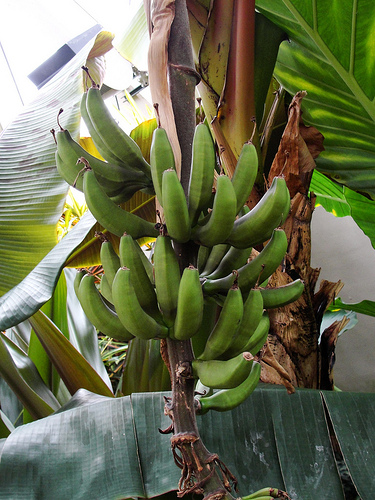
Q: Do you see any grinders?
A: No, there are no grinders.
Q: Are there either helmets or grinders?
A: No, there are no grinders or helmets.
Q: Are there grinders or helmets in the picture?
A: No, there are no grinders or helmets.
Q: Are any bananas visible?
A: Yes, there is a banana.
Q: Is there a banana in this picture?
A: Yes, there is a banana.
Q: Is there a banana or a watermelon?
A: Yes, there is a banana.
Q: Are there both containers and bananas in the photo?
A: No, there is a banana but no containers.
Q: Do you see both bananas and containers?
A: No, there is a banana but no containers.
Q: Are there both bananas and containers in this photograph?
A: No, there is a banana but no containers.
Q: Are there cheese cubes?
A: No, there are no cheese cubes.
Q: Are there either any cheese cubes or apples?
A: No, there are no cheese cubes or apples.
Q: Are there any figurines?
A: No, there are no figurines.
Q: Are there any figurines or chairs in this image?
A: No, there are no figurines or chairs.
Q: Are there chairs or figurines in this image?
A: No, there are no figurines or chairs.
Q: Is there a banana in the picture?
A: Yes, there is a banana.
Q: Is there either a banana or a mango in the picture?
A: Yes, there is a banana.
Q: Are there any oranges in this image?
A: No, there are no oranges.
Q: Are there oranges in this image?
A: No, there are no oranges.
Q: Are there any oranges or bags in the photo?
A: No, there are no oranges or bags.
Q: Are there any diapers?
A: No, there are no diapers.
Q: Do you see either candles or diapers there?
A: No, there are no diapers or candles.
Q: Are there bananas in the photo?
A: Yes, there is a banana.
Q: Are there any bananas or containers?
A: Yes, there is a banana.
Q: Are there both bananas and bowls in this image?
A: No, there is a banana but no bowls.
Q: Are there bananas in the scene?
A: Yes, there is a banana.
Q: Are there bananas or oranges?
A: Yes, there is a banana.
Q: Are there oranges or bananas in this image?
A: Yes, there is a banana.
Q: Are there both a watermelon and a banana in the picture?
A: No, there is a banana but no watermelons.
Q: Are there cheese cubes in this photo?
A: No, there are no cheese cubes.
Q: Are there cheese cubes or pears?
A: No, there are no cheese cubes or pears.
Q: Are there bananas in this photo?
A: Yes, there is a banana.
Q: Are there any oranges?
A: No, there are no oranges.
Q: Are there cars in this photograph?
A: No, there are no cars.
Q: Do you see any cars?
A: No, there are no cars.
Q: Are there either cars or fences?
A: No, there are no cars or fences.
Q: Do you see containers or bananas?
A: Yes, there is a banana.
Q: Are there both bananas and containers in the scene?
A: No, there is a banana but no containers.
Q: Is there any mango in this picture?
A: No, there are no mangoes.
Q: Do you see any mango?
A: No, there are no mangoes.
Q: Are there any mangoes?
A: No, there are no mangoes.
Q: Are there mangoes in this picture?
A: No, there are no mangoes.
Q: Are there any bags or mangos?
A: No, there are no mangos or bags.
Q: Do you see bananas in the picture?
A: Yes, there is a banana.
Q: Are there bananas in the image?
A: Yes, there is a banana.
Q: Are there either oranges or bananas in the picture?
A: Yes, there is a banana.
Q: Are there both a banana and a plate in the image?
A: No, there is a banana but no plates.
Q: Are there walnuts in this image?
A: No, there are no walnuts.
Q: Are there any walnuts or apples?
A: No, there are no walnuts or apples.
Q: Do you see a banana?
A: Yes, there is a banana.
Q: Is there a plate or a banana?
A: Yes, there is a banana.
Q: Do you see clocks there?
A: No, there are no clocks.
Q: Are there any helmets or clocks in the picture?
A: No, there are no clocks or helmets.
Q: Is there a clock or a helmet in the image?
A: No, there are no clocks or helmets.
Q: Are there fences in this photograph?
A: No, there are no fences.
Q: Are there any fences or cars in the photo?
A: No, there are no fences or cars.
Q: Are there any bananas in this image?
A: Yes, there is a banana.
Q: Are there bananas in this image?
A: Yes, there is a banana.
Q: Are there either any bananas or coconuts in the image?
A: Yes, there is a banana.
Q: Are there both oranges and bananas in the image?
A: No, there is a banana but no oranges.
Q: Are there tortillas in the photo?
A: No, there are no tortillas.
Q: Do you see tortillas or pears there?
A: No, there are no tortillas or pears.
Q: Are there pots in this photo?
A: No, there are no pots.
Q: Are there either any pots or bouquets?
A: No, there are no pots or bouquets.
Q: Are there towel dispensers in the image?
A: No, there are no towel dispensers.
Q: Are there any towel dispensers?
A: No, there are no towel dispensers.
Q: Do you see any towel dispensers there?
A: No, there are no towel dispensers.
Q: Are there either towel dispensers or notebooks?
A: No, there are no towel dispensers or notebooks.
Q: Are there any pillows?
A: No, there are no pillows.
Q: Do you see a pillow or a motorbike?
A: No, there are no pillows or motorcycles.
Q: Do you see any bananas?
A: Yes, there is a banana.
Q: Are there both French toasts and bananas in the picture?
A: No, there is a banana but no French toasts.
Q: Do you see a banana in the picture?
A: Yes, there is a banana.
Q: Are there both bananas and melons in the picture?
A: No, there is a banana but no melons.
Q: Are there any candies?
A: No, there are no candies.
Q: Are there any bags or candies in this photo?
A: No, there are no candies or bags.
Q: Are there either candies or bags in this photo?
A: No, there are no candies or bags.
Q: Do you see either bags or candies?
A: No, there are no candies or bags.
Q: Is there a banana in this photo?
A: Yes, there is a banana.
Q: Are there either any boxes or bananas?
A: Yes, there is a banana.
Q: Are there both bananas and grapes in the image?
A: No, there is a banana but no grapes.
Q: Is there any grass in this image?
A: Yes, there is grass.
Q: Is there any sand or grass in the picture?
A: Yes, there is grass.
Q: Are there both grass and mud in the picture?
A: No, there is grass but no mud.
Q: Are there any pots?
A: No, there are no pots.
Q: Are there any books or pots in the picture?
A: No, there are no pots or books.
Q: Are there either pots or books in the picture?
A: No, there are no pots or books.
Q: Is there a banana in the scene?
A: Yes, there are bananas.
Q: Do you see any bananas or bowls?
A: Yes, there are bananas.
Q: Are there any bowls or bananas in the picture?
A: Yes, there are bananas.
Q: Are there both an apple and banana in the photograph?
A: No, there are bananas but no apples.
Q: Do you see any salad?
A: No, there is no salad.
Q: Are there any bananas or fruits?
A: Yes, there is a banana.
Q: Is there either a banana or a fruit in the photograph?
A: Yes, there is a banana.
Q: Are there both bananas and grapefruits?
A: No, there is a banana but no grapefruits.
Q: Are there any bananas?
A: Yes, there is a banana.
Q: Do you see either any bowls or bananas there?
A: Yes, there is a banana.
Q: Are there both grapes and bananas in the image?
A: No, there is a banana but no grapes.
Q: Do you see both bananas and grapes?
A: No, there is a banana but no grapes.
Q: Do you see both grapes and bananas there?
A: No, there is a banana but no grapes.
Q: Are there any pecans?
A: No, there are no pecans.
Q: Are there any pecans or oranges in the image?
A: No, there are no pecans or oranges.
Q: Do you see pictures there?
A: No, there are no pictures.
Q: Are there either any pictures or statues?
A: No, there are no pictures or statues.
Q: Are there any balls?
A: No, there are no balls.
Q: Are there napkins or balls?
A: No, there are no balls or napkins.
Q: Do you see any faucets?
A: No, there are no faucets.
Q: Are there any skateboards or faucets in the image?
A: No, there are no faucets or skateboards.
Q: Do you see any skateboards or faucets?
A: No, there are no faucets or skateboards.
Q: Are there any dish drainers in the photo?
A: No, there are no dish drainers.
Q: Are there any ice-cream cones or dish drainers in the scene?
A: No, there are no dish drainers or ice-cream cones.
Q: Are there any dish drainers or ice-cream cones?
A: No, there are no dish drainers or ice-cream cones.